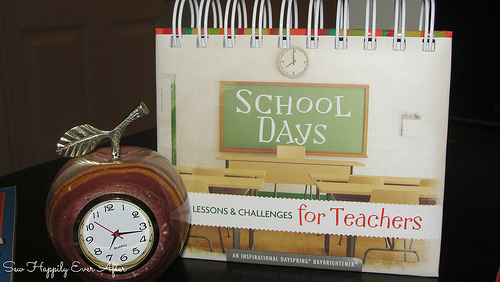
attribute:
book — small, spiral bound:
[146, 13, 450, 258]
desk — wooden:
[211, 147, 361, 176]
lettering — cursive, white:
[3, 258, 129, 278]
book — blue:
[0, 175, 37, 273]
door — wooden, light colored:
[1, 2, 338, 173]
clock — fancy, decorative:
[38, 122, 195, 274]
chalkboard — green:
[217, 79, 367, 159]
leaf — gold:
[56, 117, 106, 161]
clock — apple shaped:
[30, 97, 199, 279]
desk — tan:
[220, 153, 363, 190]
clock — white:
[264, 40, 331, 97]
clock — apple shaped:
[76, 193, 165, 271]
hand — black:
[112, 230, 150, 248]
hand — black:
[102, 237, 120, 253]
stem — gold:
[106, 105, 149, 159]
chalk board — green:
[213, 83, 362, 157]